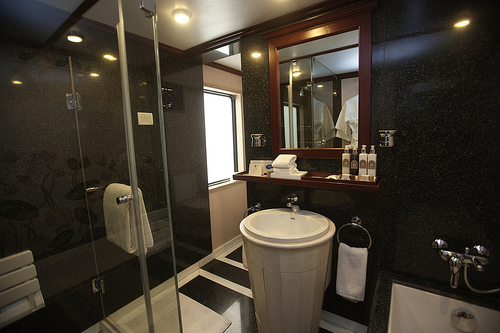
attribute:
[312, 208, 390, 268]
holder — small, silver, hand towel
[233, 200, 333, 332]
sink — tall, white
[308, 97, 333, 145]
reflection — small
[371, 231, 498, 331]
faucet — chrome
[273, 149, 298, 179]
towels — white, folded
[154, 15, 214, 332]
shower — glassy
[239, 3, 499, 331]
walls —  stone ,  granite 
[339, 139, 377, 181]
bottles — small, personal hygiene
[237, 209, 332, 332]
sink — large, white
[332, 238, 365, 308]
towel — white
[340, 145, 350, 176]
bottle — small, personal hygiene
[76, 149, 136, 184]
bottle — personal hygiene, small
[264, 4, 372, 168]
mirror — large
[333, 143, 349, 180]
bottle — small, personal hygiene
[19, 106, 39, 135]
material —  granite 